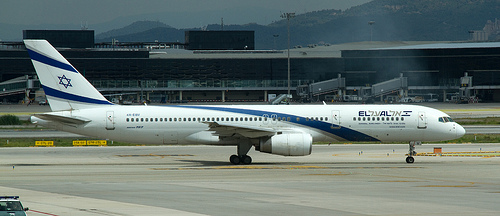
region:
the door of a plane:
[331, 105, 340, 123]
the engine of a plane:
[262, 135, 314, 160]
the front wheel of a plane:
[401, 155, 416, 163]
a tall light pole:
[277, 7, 303, 98]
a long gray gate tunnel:
[361, 77, 413, 99]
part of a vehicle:
[1, 191, 30, 214]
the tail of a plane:
[24, 35, 111, 107]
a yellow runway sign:
[32, 139, 55, 147]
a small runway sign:
[431, 147, 445, 155]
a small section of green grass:
[452, 117, 498, 123]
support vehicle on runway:
[0, 176, 35, 212]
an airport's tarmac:
[175, 171, 438, 206]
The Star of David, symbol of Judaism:
[51, 67, 76, 92]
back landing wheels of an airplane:
[215, 151, 260, 167]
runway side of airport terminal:
[165, 40, 415, 100]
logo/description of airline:
[350, 102, 415, 117]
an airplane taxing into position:
[20, 20, 480, 170]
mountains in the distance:
[100, 0, 185, 41]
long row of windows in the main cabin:
[120, 110, 201, 125]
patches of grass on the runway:
[466, 113, 496, 144]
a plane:
[18, 7, 400, 212]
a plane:
[141, 87, 333, 212]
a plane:
[51, 52, 434, 169]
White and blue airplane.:
[1, 27, 466, 157]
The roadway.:
[191, 168, 316, 214]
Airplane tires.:
[398, 143, 425, 165]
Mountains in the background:
[288, 11, 358, 34]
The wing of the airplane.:
[32, 100, 87, 145]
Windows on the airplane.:
[365, 110, 396, 121]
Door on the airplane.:
[327, 108, 347, 128]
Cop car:
[0, 190, 57, 213]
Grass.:
[7, 135, 32, 146]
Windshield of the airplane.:
[433, 106, 454, 123]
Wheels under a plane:
[230, 152, 253, 164]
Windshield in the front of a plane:
[436, 107, 457, 129]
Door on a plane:
[408, 108, 425, 133]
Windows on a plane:
[346, 111, 411, 130]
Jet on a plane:
[258, 131, 313, 166]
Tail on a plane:
[21, 99, 93, 141]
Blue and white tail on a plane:
[18, 31, 106, 122]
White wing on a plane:
[200, 110, 327, 170]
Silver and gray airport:
[57, 22, 477, 147]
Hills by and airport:
[94, 10, 247, 70]